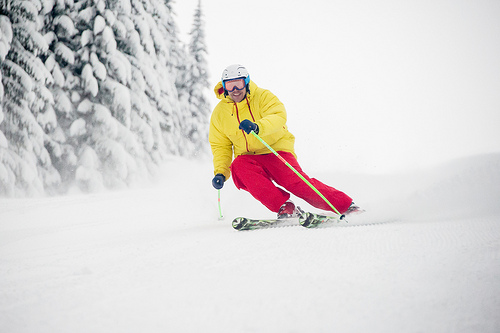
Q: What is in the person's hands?
A: Ski poles.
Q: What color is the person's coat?
A: Yellow.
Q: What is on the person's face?
A: Goggles.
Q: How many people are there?
A: 1.